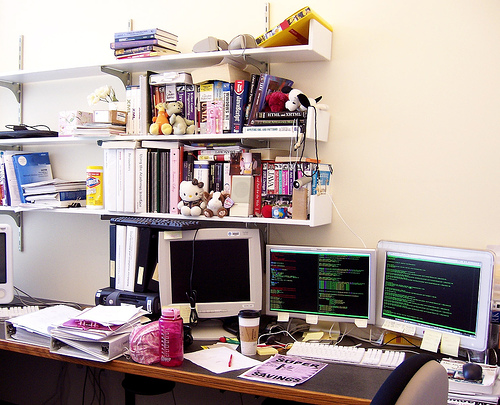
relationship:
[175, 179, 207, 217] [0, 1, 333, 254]
kitty on bookshelf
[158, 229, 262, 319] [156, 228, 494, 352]
screen in row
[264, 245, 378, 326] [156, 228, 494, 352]
screen in row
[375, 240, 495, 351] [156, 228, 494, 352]
screen in row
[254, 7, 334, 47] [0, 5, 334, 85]
box on shelf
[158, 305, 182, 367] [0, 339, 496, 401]
bottle on desk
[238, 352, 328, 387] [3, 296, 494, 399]
ad on desk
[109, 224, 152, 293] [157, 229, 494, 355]
binders next to screens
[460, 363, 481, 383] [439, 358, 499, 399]
mouse on top of books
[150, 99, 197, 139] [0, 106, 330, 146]
animals on shelf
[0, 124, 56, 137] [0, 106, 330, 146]
shoes on shelf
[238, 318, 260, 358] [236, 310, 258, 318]
cup with lid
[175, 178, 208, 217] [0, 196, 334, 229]
kitty on shelf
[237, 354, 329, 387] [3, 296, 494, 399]
paper on desk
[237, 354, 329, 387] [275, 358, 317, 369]
paper says super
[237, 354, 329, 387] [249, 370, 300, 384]
paper says savings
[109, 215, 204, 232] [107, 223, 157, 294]
keyboard on top of binders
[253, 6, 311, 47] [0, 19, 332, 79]
book on shelf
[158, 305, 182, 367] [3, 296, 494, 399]
bottle sitting on desk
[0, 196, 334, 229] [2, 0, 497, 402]
shelf attached wall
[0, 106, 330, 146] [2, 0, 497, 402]
shelf attached wall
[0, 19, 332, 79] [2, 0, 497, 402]
shelf attached wall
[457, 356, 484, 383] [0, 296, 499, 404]
mouse on table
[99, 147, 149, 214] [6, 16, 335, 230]
notebooks on shelf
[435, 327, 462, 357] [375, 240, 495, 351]
note on screen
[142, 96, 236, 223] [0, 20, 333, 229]
pets on bookshelf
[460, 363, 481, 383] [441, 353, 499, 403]
mouse on books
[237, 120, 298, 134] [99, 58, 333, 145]
book on shelf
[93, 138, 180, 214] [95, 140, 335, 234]
binders on shelf